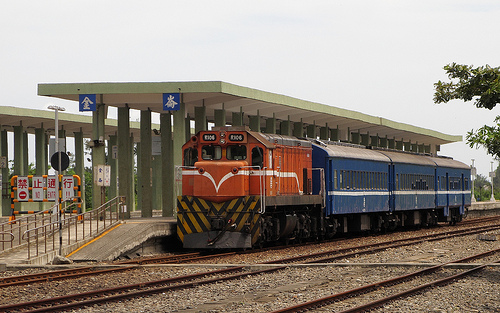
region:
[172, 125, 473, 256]
A train is sitting on some tracks.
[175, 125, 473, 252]
A train is next to a station.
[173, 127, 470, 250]
A train's colors are red, blue, white, yellow, and black.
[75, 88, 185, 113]
Two signs are hanging from a building.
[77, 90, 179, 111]
The colors of two signs are blue and white.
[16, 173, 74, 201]
Four signs are posted at a railroad station.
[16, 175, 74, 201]
The colors of four signs are white and red.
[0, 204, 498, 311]
Three sets of railroad tracks are next to a station.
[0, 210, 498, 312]
The color of three railroad tracks is brown.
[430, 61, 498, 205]
Two branches of trees are next to some railroad tracks.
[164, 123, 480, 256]
engine and cars of train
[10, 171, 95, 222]
warning signs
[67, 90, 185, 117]
train identification signs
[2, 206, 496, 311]
railroad tracks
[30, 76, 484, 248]
train depot in a Asian country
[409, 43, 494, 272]
trees alongside train tracks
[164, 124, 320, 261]
train engine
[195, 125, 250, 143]
train identification signs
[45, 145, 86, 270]
back side of a train traffic sign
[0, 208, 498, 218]
clear sky above train depot in daytime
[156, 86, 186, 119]
A blue and white sign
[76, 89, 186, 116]
Two blue and white signs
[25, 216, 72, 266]
A metal railing by a ramp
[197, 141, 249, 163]
The front window of a train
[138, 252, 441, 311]
Two sets of train tracks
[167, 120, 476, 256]
A train stopped at a station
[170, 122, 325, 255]
An orange engine of a train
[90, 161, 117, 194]
A white sign on a concrete pillar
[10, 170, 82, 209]
Red and white signs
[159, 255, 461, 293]
Gravel under railroad tracks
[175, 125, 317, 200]
red part of the train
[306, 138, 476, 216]
blue part of the train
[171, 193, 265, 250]
black and yellow bottom part of train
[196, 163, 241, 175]
headlights on the train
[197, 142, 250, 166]
windshield on the train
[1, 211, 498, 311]
train tracks near the station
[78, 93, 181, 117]
blue and white signs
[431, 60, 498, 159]
green leaves on the tree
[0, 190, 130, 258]
silver railing along the pathway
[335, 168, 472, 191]
windows on the train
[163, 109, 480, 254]
A train is in the full view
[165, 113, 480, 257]
Train is in the foreground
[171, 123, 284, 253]
The front of the train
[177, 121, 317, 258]
Top cart of the train is orange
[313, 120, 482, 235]
Lower carts of the train is blue in color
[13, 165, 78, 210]
Signs in the background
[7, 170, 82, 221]
The signs are white in color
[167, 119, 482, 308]
Train is on the train tracks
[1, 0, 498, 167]
The sky is cloudy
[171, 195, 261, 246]
Bottom of the train is yellow and black in color